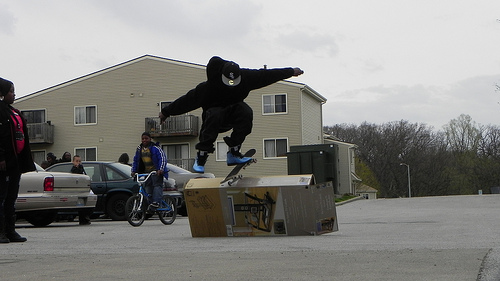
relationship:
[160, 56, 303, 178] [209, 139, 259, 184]
man on a skateboard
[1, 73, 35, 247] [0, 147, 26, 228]
person wearing pants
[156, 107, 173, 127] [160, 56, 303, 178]
hand of a man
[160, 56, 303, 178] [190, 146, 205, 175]
man wearing shoe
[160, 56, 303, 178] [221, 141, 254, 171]
man wearing shoe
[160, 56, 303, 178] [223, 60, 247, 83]
man wearing a hat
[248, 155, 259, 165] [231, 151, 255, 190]
wheel on a skateboard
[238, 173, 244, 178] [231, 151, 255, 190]
wheel on a skateboard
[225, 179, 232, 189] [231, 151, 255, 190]
wheel on a skateboard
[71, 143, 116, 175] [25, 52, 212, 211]
window on building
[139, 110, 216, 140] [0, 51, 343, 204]
balcony on building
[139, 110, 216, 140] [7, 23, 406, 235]
balcony on building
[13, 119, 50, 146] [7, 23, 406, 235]
balcony on building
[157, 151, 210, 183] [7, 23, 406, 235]
balcony on building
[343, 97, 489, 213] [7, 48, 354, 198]
trees behind building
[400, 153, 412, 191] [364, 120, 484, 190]
streetlight in front of trees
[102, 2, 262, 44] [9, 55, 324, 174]
cloud above house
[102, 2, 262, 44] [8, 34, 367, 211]
cloud above house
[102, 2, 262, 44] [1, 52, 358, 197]
cloud above house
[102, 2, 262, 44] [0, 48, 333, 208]
cloud above house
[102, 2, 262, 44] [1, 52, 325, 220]
cloud above house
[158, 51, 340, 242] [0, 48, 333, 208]
thing clouds above house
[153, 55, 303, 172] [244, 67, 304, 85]
skateboarder has two arm